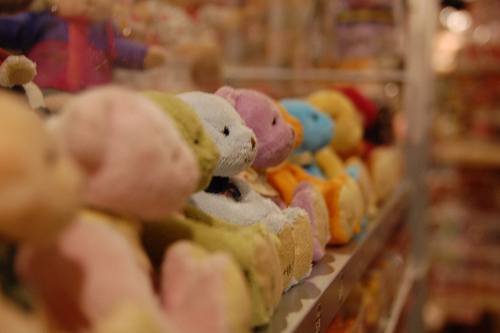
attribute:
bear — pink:
[43, 75, 236, 329]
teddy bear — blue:
[284, 90, 338, 185]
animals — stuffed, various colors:
[0, 83, 387, 327]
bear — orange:
[273, 99, 364, 244]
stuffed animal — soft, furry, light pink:
[45, 86, 251, 331]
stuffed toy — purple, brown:
[215, 86, 327, 261]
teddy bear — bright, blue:
[263, 86, 368, 238]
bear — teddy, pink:
[214, 84, 332, 265]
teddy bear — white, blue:
[59, 88, 231, 330]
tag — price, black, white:
[321, 266, 361, 321]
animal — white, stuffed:
[179, 98, 312, 289]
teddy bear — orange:
[264, 102, 348, 244]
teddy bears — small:
[3, 54, 398, 327]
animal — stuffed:
[3, 10, 160, 77]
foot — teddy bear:
[261, 227, 312, 273]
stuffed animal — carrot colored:
[256, 95, 376, 245]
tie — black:
[190, 162, 275, 220]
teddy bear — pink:
[175, 88, 321, 294]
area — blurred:
[418, 14, 493, 320]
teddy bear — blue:
[271, 97, 363, 237]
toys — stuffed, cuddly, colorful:
[4, 96, 401, 331]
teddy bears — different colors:
[1, 69, 421, 315]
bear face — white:
[180, 88, 265, 183]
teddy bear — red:
[337, 79, 399, 201]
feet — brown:
[370, 146, 405, 201]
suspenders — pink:
[64, 8, 128, 102]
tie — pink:
[67, 15, 87, 113]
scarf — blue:
[209, 170, 254, 195]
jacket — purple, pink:
[234, 168, 284, 197]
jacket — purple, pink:
[132, 211, 202, 262]